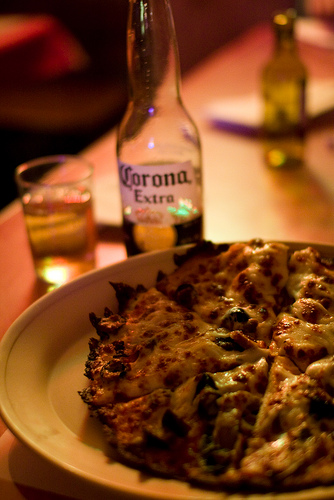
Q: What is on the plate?
A: The plate has food on it.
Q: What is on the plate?
A: Pizza is on the plate.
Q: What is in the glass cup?
A: A drink is in the glass cup.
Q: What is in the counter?
A: The counter has drinks and a plate on it.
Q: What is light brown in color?
A: The counter is a light brown color.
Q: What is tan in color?
A: The drink is a tan color.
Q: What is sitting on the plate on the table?
A: Pizza sitting on plate on table.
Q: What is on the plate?
A: Slices of pizza on plate.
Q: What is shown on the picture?
A: The Edge of plate the pizza sitting on.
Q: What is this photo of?
A: A table.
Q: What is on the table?
A: A plate.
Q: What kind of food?
A: Pizza.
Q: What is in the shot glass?
A: Liquor.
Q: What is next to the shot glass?
A: A bottle.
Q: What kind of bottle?
A: Beer bottle.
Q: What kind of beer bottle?
A: Corona.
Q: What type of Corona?
A: Extra.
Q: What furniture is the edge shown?
A: Long table.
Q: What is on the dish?
A: Food.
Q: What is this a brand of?
A: Beer.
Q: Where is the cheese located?
A: On food.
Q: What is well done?
A: Crust.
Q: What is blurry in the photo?
A: Background.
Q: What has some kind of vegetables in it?
A: Food.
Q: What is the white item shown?
A: Plate.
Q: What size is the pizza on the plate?
A: Small.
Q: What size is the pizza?
A: Small.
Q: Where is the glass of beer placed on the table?
A: Next to the Corona Extra bottle.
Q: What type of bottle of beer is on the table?
A: Corona Extra.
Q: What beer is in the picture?
A: Corona Extra.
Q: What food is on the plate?
A: Pizza.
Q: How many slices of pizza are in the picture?
A: Six.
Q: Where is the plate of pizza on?
A: The table.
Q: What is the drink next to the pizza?
A: Beer.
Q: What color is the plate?
A: White.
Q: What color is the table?
A: Brown.